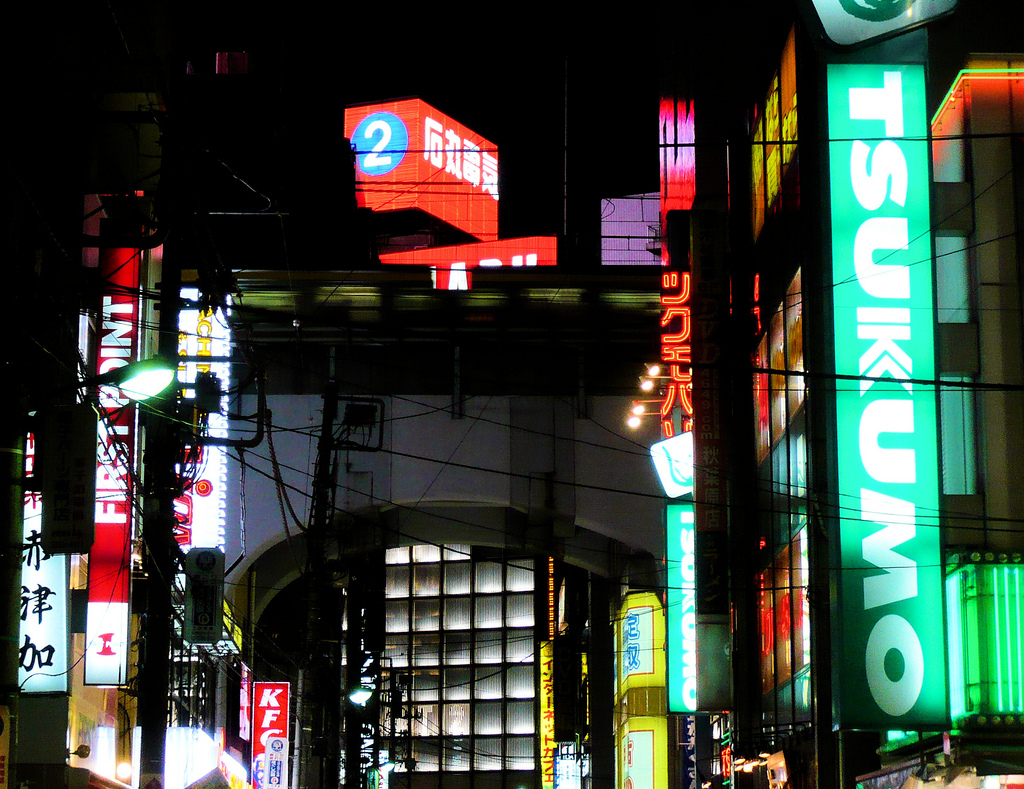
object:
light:
[120, 370, 175, 401]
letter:
[848, 72, 905, 138]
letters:
[842, 138, 910, 212]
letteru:
[856, 217, 917, 304]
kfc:
[258, 688, 283, 747]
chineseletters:
[20, 634, 54, 671]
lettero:
[866, 614, 922, 717]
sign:
[830, 59, 940, 726]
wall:
[14, 398, 387, 661]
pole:
[143, 396, 172, 784]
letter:
[849, 139, 908, 211]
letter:
[859, 399, 916, 484]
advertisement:
[252, 681, 289, 784]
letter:
[22, 530, 50, 571]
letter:
[29, 584, 56, 624]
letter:
[21, 586, 30, 620]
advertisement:
[20, 427, 69, 692]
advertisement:
[345, 98, 499, 242]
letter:
[424, 116, 443, 168]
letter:
[444, 129, 462, 180]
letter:
[463, 140, 481, 187]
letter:
[481, 152, 499, 202]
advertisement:
[826, 0, 946, 731]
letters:
[824, 62, 959, 771]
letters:
[856, 308, 913, 396]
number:
[864, 614, 924, 717]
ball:
[350, 113, 409, 175]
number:
[364, 120, 391, 166]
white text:
[258, 689, 283, 728]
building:
[342, 98, 559, 272]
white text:
[422, 120, 499, 203]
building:
[11, 200, 382, 754]